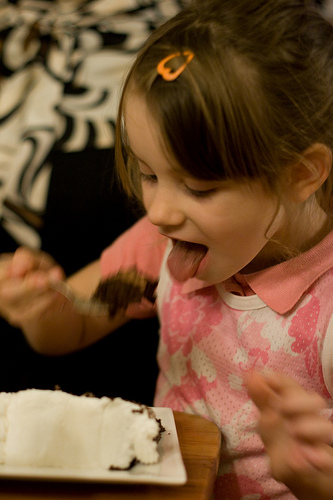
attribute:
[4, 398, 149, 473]
slice of cake — white, chocolate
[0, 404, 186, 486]
plate — square, white, rectangular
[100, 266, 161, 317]
piece of cake — chocolate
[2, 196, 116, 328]
fork — stainless steel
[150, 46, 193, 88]
barrett — orange, heart shaped, metal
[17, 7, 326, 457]
girl — little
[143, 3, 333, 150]
hair — brown, blonde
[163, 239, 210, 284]
tongue — pink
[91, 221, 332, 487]
dress — pink, white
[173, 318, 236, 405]
patterns — white, pink, floral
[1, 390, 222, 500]
table — brown, wooden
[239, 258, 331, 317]
collar — pink, peach pink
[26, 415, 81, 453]
icing — white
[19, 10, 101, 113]
patterns — blurred, black, white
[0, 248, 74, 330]
hand — blurry